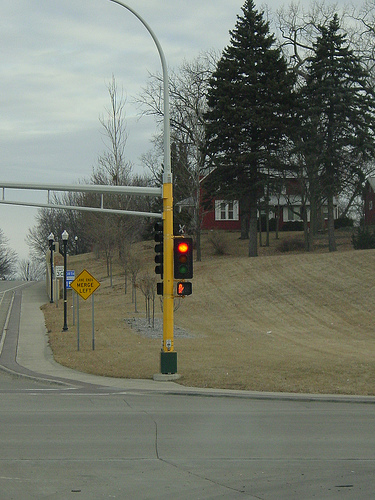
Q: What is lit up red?
A: Traffic light.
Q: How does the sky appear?
A: Overcast.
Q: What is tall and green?
A: Trees.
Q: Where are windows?
A: On the house.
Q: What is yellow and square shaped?
A: Sign.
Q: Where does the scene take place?
A: Near a street.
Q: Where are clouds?
A: In the sky.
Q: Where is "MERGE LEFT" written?
A: On yellow sign.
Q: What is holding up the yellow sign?
A: Two posts.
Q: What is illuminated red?
A: Traffic control light.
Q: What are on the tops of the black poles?
A: Street lights.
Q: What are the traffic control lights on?
A: Pole.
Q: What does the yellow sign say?
A: Lane Ends Merge Left.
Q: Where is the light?
A: On a pole.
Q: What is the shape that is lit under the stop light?
A: A hand.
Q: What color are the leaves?
A: Green.